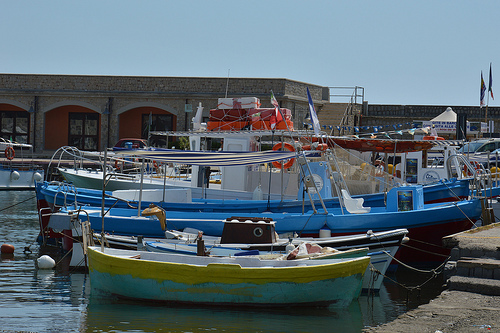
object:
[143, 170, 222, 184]
boat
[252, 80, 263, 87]
brick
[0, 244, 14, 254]
buoy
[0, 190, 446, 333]
water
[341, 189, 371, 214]
boat seat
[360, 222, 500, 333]
walkway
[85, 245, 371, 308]
boat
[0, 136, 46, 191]
boat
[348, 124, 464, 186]
boat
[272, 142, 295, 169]
life preserver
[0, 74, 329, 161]
wall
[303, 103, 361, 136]
stairs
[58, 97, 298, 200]
boat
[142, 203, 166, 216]
orange cones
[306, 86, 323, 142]
flag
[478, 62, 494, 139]
flags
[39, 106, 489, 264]
boat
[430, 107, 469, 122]
cone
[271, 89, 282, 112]
cone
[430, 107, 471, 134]
tent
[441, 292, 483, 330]
stones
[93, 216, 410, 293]
boat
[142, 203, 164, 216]
cone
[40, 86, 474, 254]
boat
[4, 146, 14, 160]
life buoy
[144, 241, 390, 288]
boat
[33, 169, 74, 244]
boat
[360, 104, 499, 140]
building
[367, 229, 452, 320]
rope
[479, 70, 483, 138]
poles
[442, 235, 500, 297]
stair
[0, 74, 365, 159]
building